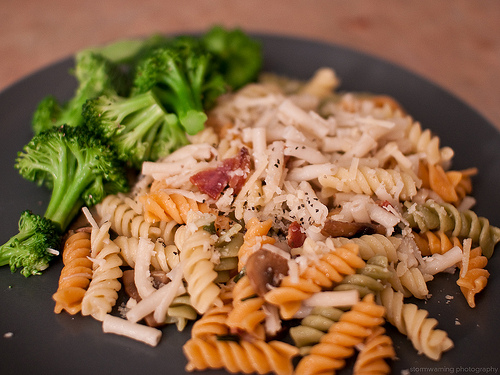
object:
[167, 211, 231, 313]
rotini pasta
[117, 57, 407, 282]
salad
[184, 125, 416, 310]
pasta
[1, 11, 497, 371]
plate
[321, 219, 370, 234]
bacon